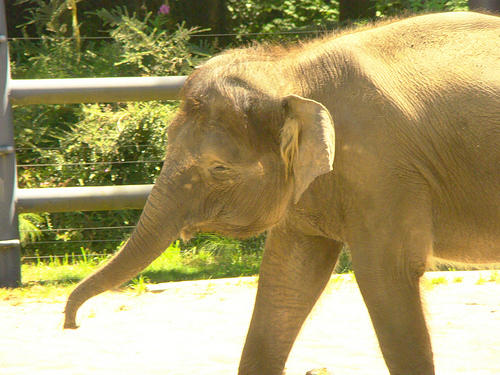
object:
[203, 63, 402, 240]
elephants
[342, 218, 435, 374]
leg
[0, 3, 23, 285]
pole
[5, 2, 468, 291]
green area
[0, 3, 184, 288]
fence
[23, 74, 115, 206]
fence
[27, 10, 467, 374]
elephant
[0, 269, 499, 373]
ground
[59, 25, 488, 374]
elephants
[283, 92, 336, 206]
ear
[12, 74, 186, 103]
pole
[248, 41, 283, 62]
hair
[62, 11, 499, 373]
elephant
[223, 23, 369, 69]
hair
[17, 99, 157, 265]
bush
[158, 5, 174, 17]
flower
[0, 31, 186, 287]
pen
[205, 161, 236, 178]
eye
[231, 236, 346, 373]
leg